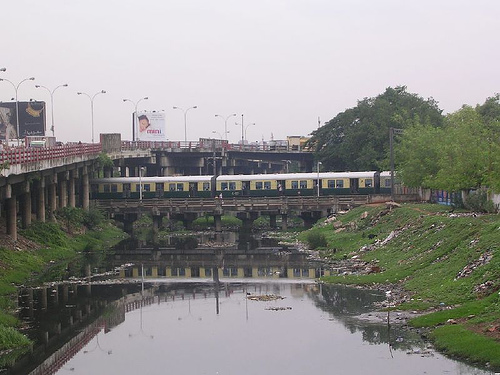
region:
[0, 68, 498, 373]
highway over pass with train underneeth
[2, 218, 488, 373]
dirty water under train tracks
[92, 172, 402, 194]
yellow and green train going over track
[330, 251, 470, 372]
garbage on the river banks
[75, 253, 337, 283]
reflection of train in the water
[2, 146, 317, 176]
highway overpass with red fence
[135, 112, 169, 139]
advertise poster in the air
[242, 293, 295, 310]
dirt and plastic in water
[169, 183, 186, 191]
window in the yellow and green train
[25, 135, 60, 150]
truck and car on over pass high way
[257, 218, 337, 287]
the river is dirty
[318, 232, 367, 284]
the river is dirty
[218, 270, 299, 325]
the river is dirty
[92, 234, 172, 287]
the river is dirty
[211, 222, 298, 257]
the river is dirty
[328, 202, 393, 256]
trash by the riverside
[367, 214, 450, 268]
trash by the riverside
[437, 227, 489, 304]
trash by the riverside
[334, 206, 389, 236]
trash by the riverside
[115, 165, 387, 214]
a train in the bridge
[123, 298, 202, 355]
the water is murky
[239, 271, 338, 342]
the water is murky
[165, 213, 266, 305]
the water is murky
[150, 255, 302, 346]
the water is murky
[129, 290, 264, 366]
the water is murky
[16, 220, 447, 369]
This is a pool of water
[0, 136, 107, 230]
This is a building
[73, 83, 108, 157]
a street light pole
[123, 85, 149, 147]
a street light pole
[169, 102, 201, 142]
a street light pole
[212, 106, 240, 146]
a street light pole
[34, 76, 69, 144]
a street light pole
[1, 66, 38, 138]
a street light pole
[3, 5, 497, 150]
The sky is overcast.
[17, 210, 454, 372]
The water is murky.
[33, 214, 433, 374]
The water is calm.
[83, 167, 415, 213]
The train is on the tracks.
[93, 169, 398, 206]
The train is over the water.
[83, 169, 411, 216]
The train is on the bridge.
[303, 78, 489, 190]
The trees are leafy.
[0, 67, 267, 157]
The street lights are off.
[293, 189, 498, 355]
The terrain is grassy and rocky.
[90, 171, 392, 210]
The train is yellow.